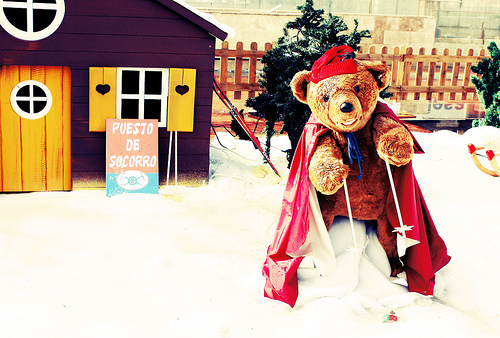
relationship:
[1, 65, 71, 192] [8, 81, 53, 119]
door with round window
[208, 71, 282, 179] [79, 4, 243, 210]
skis propped on house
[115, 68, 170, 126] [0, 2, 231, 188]
window on house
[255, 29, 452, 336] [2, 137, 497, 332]
bear in snow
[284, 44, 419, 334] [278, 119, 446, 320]
bear wearing cape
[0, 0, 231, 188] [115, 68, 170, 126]
house with window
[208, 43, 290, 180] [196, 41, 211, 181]
skis leaning against wall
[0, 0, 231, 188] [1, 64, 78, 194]
house has door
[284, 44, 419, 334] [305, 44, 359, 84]
bear has red hat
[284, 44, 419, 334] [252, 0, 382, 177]
bear in front of tree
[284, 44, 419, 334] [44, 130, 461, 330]
bear on snow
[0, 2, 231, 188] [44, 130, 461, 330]
house on snow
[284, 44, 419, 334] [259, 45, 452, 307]
bear on snow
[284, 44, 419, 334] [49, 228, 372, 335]
bear in snow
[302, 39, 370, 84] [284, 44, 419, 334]
red hat worn by bear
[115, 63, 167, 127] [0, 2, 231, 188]
window on house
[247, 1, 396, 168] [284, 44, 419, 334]
tree behind bear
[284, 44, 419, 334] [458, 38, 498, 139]
bear front tree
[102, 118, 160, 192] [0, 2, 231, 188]
sign in front of house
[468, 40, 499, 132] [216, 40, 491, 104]
tree in front of fence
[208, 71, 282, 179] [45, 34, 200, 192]
skis on house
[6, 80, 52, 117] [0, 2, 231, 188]
round window on house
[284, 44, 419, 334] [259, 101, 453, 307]
bear wears cape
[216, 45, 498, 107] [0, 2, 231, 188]
fence behind house